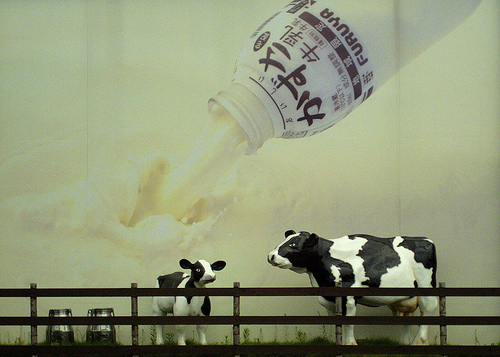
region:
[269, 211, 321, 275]
head of a cow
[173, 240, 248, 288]
of a cow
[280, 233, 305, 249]
eye of a cow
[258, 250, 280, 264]
mouth of a cow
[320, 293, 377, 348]
leg of a cow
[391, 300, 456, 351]
leg of a cow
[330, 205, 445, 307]
body of a cow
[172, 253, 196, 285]
an ear of a cow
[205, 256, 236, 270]
an ear of a cow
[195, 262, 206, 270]
an eye of a cow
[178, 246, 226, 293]
head of a cow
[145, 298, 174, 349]
leg of a cow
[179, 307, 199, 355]
leg of a cow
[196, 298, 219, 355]
leg of a cow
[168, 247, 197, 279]
ear of a cow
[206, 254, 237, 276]
ear of a cow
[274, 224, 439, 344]
a large cow statue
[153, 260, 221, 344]
a small cow statue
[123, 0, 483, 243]
a photo of pouring milk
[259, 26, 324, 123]
the bottle has asian characters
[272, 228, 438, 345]
the cow is black and white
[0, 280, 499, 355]
the fence is made of wood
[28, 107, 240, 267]
milk being poured out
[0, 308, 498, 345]
grass painted on billboard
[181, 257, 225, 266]
the cow has two ears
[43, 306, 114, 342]
the tubs are next to cow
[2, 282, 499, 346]
a wooden brown fence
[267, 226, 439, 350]
a black and white cow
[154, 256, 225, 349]
a black and white calf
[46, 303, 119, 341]
a silver milk bucket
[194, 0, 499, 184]
a bottle on a wall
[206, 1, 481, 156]
a white bottle on a wall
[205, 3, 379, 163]
a white bottle with writing on it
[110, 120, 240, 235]
white milk coming out of bottle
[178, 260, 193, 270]
a black ear on a calf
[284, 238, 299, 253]
a left eye on a cow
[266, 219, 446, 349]
little black and white cow figurine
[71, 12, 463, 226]
little plastic bottle of milk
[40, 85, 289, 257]
milk pouring out of bottle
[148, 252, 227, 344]
little figurine of baby cow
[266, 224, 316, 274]
black and white head of cow statue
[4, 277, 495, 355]
section of brown miniature fence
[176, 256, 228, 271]
two black ears on little cow statue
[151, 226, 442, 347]
two resin black and white cow statues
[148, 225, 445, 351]
two fake cows behind fence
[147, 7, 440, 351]
two statues in front of milk advertisement